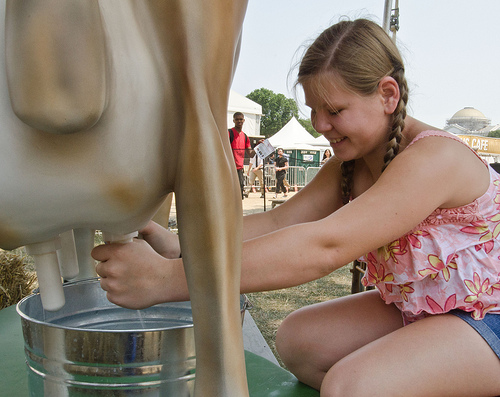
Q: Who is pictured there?
A: A girl.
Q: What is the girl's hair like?
A: Braided.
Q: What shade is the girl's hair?
A: Blonde.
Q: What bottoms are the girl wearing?
A: Shorts.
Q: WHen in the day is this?
A: Afternoon.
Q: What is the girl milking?
A: Cow.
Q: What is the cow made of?
A: Plastic.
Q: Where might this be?
A: Carnival.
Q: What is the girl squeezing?
A: Utter.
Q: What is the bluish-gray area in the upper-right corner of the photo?
A: The sky.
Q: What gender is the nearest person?
A: Female.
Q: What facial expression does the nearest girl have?
A: A smile.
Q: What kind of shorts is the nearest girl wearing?
A: Jean shorts.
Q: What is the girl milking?
A: A fake cow.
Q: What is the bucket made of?
A: Metal.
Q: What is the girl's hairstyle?
A: Pigtails.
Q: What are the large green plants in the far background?
A: Trees.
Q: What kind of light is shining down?
A: Sunlight.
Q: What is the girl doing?
A: Milking the cow.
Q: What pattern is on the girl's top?
A: Floral.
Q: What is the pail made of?
A: Metal.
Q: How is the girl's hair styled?
A: Braids.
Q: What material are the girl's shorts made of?
A: Denim.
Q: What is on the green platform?
A: Fake cow.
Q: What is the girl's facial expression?
A: Smile.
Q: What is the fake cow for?
A: Practicing milking.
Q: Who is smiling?
A: The girl in the pigtails.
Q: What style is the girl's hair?
A: Pigtails.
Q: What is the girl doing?
A: Milking a cow.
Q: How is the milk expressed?
A: Squeezing the udders.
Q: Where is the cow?
A: To the left of the girl.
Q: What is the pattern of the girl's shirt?
A: Floral.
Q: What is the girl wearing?
A: A tank top and shorts.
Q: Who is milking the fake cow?
A: A girl.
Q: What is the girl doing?
A: Milking a fake cow.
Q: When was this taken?
A: Daytime.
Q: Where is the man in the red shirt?
A: Behind a rope fence.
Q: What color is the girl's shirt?
A: Pink and yellow.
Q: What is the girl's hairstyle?
A: Two braids.